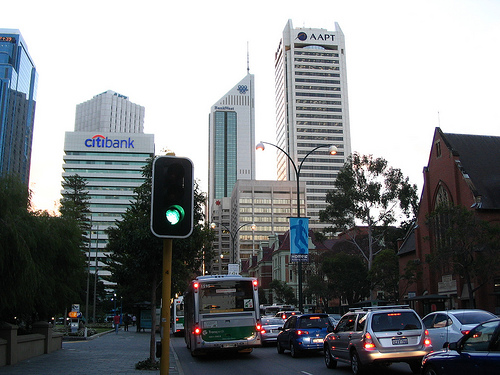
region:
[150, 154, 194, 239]
Green light at an intersection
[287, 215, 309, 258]
Banner hung on streetlight pole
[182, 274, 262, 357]
Back of a passenger bus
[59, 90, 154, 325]
Large citibank office building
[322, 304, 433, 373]
Silver station wagon in traffic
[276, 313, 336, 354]
Small blue car in traffic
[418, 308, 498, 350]
White passenger car sitting in traffic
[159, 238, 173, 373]
Utility pole supporting streetlight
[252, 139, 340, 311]
Overhead outdoor lighting mounted on sidewalk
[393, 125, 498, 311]
Front of brick church building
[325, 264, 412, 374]
Car parked on pavement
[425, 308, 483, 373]
Car parked on pavement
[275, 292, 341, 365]
Car parked on pavement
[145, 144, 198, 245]
Green traffic light on pole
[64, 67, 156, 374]
Large building in the city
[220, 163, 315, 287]
Large building in the city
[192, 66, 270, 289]
Large building in the city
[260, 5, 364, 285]
Large building in the city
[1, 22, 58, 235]
Large building in the city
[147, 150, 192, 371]
a green traffic light on a yellow pole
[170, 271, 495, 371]
vehicles showing their red lights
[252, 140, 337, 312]
two illuminated street lamps on a single pole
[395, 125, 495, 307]
a large red building resembling a place of worship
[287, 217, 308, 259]
banner with a human figure in silhouette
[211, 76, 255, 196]
tall building with a pointed roof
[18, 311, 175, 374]
pedestrians on a wide sidewalk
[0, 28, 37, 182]
upper section of a tall blue building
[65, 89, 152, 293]
blue and red logo on a building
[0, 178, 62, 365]
dark trees behind a low wall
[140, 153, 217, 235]
this is a traffic light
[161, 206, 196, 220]
the light is indicating green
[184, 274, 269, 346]
this is a bus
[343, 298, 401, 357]
this is a car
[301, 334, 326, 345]
the car is blue in color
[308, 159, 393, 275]
this is a tree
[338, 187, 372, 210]
the leaves are green in color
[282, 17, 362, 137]
this is a building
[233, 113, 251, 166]
this is the wall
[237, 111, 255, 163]
the wall is white in color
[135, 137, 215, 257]
a green traffic light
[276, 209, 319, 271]
a blue banner on pole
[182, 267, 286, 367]
the back end of a bus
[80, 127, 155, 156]
Citibank logo on building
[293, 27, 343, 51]
AAPT on top of building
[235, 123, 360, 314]
a light pole with two lights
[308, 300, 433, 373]
a silver suv in traffic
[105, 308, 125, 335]
a person in red and blue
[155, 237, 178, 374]
a yellow pole with traffic light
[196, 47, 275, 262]
a white building with slanted top